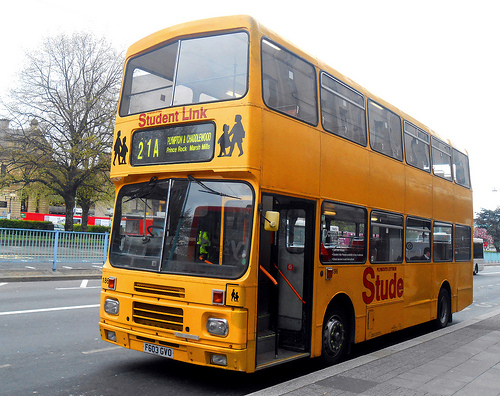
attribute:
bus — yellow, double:
[100, 29, 489, 375]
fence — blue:
[1, 212, 109, 268]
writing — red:
[355, 256, 435, 306]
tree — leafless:
[23, 35, 118, 251]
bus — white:
[423, 229, 488, 280]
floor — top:
[134, 41, 491, 215]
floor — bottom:
[110, 191, 448, 199]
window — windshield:
[112, 164, 243, 293]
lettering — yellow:
[164, 132, 215, 165]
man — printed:
[218, 112, 255, 160]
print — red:
[361, 269, 410, 307]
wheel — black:
[320, 291, 365, 362]